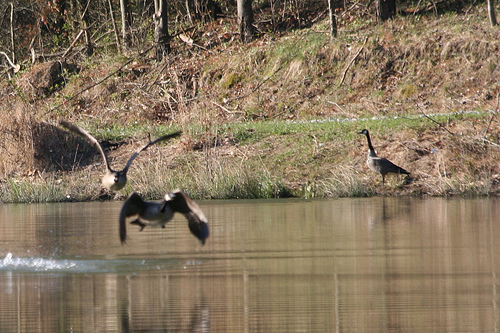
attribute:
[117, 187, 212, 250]
bird — flapping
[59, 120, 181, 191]
bird — flapping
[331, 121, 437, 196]
bird — standing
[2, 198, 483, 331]
water — calm, reflective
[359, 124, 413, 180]
bird — flapping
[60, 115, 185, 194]
bird — flapping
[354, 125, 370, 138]
face — black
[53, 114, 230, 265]
birds — flying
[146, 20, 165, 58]
tree trunk — partly seen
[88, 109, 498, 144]
grass — green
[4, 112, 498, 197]
grass — tall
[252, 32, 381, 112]
tree limbs — dead